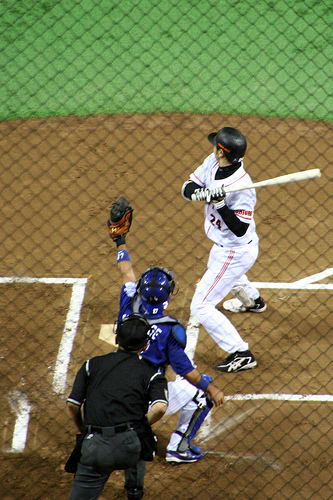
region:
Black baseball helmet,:
[206, 126, 249, 161]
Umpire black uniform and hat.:
[70, 314, 169, 493]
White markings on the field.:
[8, 264, 71, 384]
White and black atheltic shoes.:
[213, 350, 258, 372]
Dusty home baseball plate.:
[97, 321, 115, 350]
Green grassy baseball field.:
[9, 7, 318, 100]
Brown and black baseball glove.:
[106, 196, 135, 240]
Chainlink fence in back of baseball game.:
[0, 2, 331, 495]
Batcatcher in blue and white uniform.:
[109, 251, 226, 465]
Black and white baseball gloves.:
[186, 185, 227, 203]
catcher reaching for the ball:
[85, 192, 220, 466]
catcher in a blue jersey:
[100, 195, 229, 465]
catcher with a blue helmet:
[88, 195, 224, 466]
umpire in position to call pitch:
[50, 308, 171, 498]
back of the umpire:
[54, 307, 168, 499]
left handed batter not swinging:
[179, 121, 327, 377]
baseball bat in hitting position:
[187, 166, 327, 204]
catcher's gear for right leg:
[176, 382, 217, 468]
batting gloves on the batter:
[181, 182, 231, 211]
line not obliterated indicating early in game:
[221, 390, 332, 406]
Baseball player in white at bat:
[178, 123, 268, 372]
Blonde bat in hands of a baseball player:
[189, 166, 320, 198]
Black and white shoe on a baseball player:
[213, 348, 255, 372]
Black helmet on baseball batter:
[205, 124, 248, 158]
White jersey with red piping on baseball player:
[188, 152, 255, 246]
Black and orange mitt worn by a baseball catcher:
[104, 194, 132, 241]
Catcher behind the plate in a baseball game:
[114, 235, 225, 462]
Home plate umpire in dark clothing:
[62, 311, 168, 498]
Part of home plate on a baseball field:
[96, 321, 114, 342]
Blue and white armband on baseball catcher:
[114, 249, 129, 261]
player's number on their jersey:
[208, 213, 222, 229]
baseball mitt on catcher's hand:
[107, 196, 134, 242]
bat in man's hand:
[190, 166, 322, 201]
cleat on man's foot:
[211, 348, 258, 370]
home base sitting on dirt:
[97, 320, 127, 347]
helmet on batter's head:
[206, 127, 248, 162]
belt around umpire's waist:
[84, 420, 142, 436]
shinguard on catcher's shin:
[177, 402, 214, 457]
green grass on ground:
[0, 0, 330, 127]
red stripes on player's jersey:
[199, 249, 235, 322]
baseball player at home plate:
[167, 107, 319, 388]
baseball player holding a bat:
[176, 111, 316, 412]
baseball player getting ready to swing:
[164, 116, 306, 404]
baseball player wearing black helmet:
[191, 112, 253, 166]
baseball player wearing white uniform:
[158, 133, 274, 384]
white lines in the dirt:
[6, 256, 123, 427]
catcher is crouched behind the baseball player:
[90, 189, 246, 461]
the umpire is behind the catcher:
[37, 298, 166, 491]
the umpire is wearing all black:
[29, 299, 187, 497]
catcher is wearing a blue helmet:
[134, 259, 208, 316]